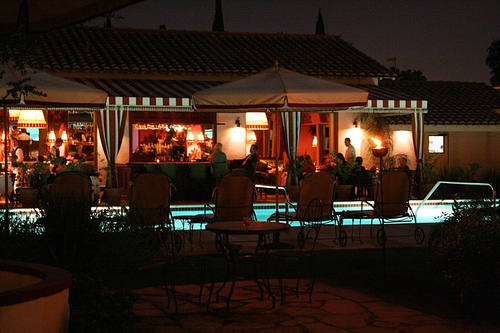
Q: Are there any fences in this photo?
A: No, there are no fences.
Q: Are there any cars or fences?
A: No, there are no fences or cars.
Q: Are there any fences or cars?
A: No, there are no fences or cars.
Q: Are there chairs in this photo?
A: Yes, there is a chair.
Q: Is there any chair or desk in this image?
A: Yes, there is a chair.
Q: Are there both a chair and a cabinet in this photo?
A: No, there is a chair but no cabinets.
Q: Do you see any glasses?
A: No, there are no glasses.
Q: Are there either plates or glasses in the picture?
A: No, there are no glasses or plates.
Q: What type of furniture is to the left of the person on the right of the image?
A: The piece of furniture is a chair.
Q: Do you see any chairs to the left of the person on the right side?
A: Yes, there is a chair to the left of the person.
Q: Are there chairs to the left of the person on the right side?
A: Yes, there is a chair to the left of the person.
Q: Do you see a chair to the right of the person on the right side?
A: No, the chair is to the left of the person.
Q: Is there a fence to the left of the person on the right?
A: No, there is a chair to the left of the person.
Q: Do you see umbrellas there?
A: Yes, there is an umbrella.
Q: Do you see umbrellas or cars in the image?
A: Yes, there is an umbrella.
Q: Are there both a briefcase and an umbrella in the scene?
A: No, there is an umbrella but no briefcases.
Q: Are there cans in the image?
A: No, there are no cans.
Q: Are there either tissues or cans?
A: No, there are no cans or tissues.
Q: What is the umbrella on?
A: The umbrella is on the chair.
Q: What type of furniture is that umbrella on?
A: The umbrella is on the chair.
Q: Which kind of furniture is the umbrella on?
A: The umbrella is on the chair.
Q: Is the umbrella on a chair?
A: Yes, the umbrella is on a chair.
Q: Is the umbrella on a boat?
A: No, the umbrella is on a chair.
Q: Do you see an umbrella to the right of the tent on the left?
A: Yes, there is an umbrella to the right of the tent.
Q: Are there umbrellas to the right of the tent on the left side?
A: Yes, there is an umbrella to the right of the tent.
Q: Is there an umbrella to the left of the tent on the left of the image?
A: No, the umbrella is to the right of the tent.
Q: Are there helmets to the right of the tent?
A: No, there is an umbrella to the right of the tent.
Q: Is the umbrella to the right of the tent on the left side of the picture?
A: Yes, the umbrella is to the right of the tent.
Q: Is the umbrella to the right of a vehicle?
A: No, the umbrella is to the right of the tent.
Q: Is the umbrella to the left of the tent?
A: No, the umbrella is to the right of the tent.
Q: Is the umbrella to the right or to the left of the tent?
A: The umbrella is to the right of the tent.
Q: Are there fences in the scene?
A: No, there are no fences.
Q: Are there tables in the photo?
A: Yes, there is a table.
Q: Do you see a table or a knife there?
A: Yes, there is a table.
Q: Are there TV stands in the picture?
A: No, there are no TV stands.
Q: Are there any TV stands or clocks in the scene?
A: No, there are no TV stands or clocks.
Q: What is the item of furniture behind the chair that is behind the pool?
A: The piece of furniture is a table.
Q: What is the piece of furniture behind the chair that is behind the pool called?
A: The piece of furniture is a table.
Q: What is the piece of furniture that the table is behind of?
A: The piece of furniture is a chair.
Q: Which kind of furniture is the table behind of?
A: The table is behind the chair.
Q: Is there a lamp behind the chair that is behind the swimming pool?
A: No, there is a table behind the chair.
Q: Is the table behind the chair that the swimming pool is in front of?
A: Yes, the table is behind the chair.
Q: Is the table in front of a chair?
A: No, the table is behind a chair.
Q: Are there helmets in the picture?
A: No, there are no helmets.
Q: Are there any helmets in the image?
A: No, there are no helmets.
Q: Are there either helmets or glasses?
A: No, there are no helmets or glasses.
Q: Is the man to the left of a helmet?
A: No, the man is to the left of the curtain.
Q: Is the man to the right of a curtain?
A: No, the man is to the left of a curtain.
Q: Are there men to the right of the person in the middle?
A: Yes, there is a man to the right of the person.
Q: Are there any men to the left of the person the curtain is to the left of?
A: No, the man is to the right of the person.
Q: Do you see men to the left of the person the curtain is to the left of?
A: No, the man is to the right of the person.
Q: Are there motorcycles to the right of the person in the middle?
A: No, there is a man to the right of the person.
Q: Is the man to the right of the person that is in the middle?
A: Yes, the man is to the right of the person.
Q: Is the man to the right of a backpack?
A: No, the man is to the right of the person.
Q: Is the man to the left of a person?
A: No, the man is to the right of a person.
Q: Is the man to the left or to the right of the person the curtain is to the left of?
A: The man is to the right of the person.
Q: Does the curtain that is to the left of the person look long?
A: Yes, the curtain is long.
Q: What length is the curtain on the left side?
A: The curtain is long.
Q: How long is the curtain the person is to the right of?
A: The curtain is long.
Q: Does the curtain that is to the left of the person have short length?
A: No, the curtain is long.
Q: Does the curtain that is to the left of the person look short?
A: No, the curtain is long.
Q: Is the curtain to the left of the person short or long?
A: The curtain is long.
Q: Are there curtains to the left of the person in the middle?
A: Yes, there is a curtain to the left of the person.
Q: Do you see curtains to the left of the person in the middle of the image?
A: Yes, there is a curtain to the left of the person.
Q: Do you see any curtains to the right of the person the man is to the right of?
A: No, the curtain is to the left of the person.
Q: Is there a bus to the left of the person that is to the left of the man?
A: No, there is a curtain to the left of the person.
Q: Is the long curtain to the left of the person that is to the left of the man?
A: Yes, the curtain is to the left of the person.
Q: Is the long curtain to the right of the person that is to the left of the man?
A: No, the curtain is to the left of the person.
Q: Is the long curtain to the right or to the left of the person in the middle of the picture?
A: The curtain is to the left of the person.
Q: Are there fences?
A: No, there are no fences.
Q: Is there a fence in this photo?
A: No, there are no fences.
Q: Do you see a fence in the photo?
A: No, there are no fences.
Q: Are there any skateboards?
A: No, there are no skateboards.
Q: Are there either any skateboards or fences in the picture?
A: No, there are no skateboards or fences.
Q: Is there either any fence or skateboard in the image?
A: No, there are no skateboards or fences.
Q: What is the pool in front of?
A: The pool is in front of the chair.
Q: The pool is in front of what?
A: The pool is in front of the chair.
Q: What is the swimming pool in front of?
A: The pool is in front of the chair.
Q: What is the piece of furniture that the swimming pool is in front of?
A: The piece of furniture is a chair.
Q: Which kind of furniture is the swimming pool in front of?
A: The swimming pool is in front of the chair.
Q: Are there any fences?
A: No, there are no fences.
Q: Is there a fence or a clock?
A: No, there are no fences or clocks.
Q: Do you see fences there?
A: No, there are no fences.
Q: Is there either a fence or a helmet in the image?
A: No, there are no fences or helmets.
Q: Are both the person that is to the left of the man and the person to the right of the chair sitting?
A: Yes, both the person and the person are sitting.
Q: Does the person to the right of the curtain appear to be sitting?
A: Yes, the person is sitting.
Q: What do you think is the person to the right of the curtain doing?
A: The person is sitting.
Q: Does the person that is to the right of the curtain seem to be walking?
A: No, the person is sitting.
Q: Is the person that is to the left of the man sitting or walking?
A: The person is sitting.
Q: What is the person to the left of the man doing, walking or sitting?
A: The person is sitting.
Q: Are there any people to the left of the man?
A: Yes, there is a person to the left of the man.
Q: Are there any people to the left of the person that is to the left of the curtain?
A: Yes, there is a person to the left of the man.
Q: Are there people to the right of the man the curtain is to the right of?
A: No, the person is to the left of the man.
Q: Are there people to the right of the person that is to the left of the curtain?
A: No, the person is to the left of the man.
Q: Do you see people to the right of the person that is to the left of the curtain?
A: No, the person is to the left of the man.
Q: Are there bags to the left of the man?
A: No, there is a person to the left of the man.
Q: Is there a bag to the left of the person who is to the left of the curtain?
A: No, there is a person to the left of the man.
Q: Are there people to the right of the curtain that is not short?
A: Yes, there is a person to the right of the curtain.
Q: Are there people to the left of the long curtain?
A: No, the person is to the right of the curtain.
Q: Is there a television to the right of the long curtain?
A: No, there is a person to the right of the curtain.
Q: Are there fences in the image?
A: No, there are no fences.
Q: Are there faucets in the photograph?
A: No, there are no faucets.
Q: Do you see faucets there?
A: No, there are no faucets.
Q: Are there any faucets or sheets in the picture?
A: No, there are no faucets or sheets.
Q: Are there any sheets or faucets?
A: No, there are no faucets or sheets.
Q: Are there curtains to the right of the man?
A: Yes, there is a curtain to the right of the man.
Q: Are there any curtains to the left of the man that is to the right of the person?
A: No, the curtain is to the right of the man.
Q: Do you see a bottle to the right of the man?
A: No, there is a curtain to the right of the man.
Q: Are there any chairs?
A: Yes, there is a chair.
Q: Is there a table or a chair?
A: Yes, there is a chair.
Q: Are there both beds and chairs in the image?
A: No, there is a chair but no beds.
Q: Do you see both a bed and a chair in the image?
A: No, there is a chair but no beds.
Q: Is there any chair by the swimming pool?
A: Yes, there is a chair by the swimming pool.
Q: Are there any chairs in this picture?
A: Yes, there is a chair.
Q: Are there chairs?
A: Yes, there is a chair.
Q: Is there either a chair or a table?
A: Yes, there is a chair.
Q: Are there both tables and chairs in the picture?
A: Yes, there are both a chair and a table.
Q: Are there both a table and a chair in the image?
A: Yes, there are both a chair and a table.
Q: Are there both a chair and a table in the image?
A: Yes, there are both a chair and a table.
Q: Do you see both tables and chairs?
A: Yes, there are both a chair and a table.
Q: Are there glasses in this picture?
A: No, there are no glasses.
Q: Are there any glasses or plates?
A: No, there are no glasses or plates.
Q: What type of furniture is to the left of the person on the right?
A: The piece of furniture is a chair.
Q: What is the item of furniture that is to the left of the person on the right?
A: The piece of furniture is a chair.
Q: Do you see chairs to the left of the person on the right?
A: Yes, there is a chair to the left of the person.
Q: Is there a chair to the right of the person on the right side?
A: No, the chair is to the left of the person.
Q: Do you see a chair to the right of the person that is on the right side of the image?
A: No, the chair is to the left of the person.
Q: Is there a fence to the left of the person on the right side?
A: No, there is a chair to the left of the person.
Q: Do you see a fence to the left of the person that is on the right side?
A: No, there is a chair to the left of the person.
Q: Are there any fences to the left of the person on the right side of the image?
A: No, there is a chair to the left of the person.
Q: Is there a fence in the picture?
A: No, there are no fences.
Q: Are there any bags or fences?
A: No, there are no fences or bags.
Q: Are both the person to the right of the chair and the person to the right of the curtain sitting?
A: Yes, both the person and the person are sitting.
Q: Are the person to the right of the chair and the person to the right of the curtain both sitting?
A: Yes, both the person and the person are sitting.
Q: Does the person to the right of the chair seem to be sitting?
A: Yes, the person is sitting.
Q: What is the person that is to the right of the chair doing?
A: The person is sitting.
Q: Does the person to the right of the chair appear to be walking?
A: No, the person is sitting.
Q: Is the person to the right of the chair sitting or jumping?
A: The person is sitting.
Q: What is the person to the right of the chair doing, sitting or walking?
A: The person is sitting.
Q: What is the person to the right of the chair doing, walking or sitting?
A: The person is sitting.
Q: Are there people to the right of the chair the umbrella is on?
A: Yes, there is a person to the right of the chair.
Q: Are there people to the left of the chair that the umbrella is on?
A: No, the person is to the right of the chair.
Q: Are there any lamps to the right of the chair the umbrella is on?
A: No, there is a person to the right of the chair.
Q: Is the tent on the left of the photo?
A: Yes, the tent is on the left of the image.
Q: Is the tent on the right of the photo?
A: No, the tent is on the left of the image.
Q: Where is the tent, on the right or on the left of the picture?
A: The tent is on the left of the image.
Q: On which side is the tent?
A: The tent is on the left of the image.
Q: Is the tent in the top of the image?
A: Yes, the tent is in the top of the image.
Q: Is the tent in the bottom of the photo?
A: No, the tent is in the top of the image.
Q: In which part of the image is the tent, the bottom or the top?
A: The tent is in the top of the image.